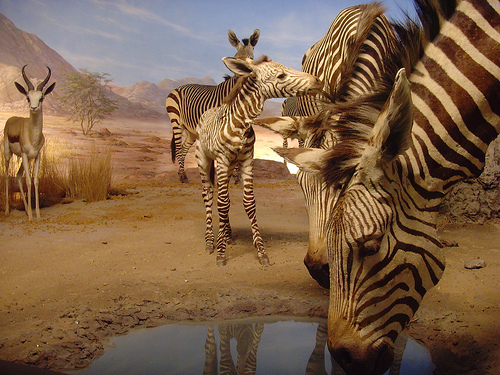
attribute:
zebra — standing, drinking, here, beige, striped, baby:
[191, 28, 359, 218]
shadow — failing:
[189, 291, 249, 374]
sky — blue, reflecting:
[98, 23, 155, 66]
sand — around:
[118, 220, 187, 260]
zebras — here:
[221, 44, 473, 291]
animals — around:
[287, 97, 393, 280]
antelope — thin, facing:
[11, 77, 79, 170]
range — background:
[62, 67, 242, 129]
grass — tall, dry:
[68, 149, 117, 202]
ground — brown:
[85, 194, 187, 278]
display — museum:
[35, 21, 444, 363]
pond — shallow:
[190, 322, 272, 374]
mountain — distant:
[23, 31, 84, 70]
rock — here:
[456, 238, 497, 283]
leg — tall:
[209, 166, 244, 237]